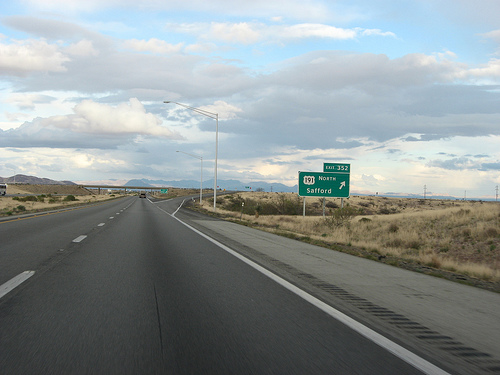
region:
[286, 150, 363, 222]
green and white traffic sign on side of road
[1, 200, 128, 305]
white dash lines on highway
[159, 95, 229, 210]
street lamps on side of highway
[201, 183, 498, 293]
field of green and yellow grass on side of highway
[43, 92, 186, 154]
white clouds in light blue sky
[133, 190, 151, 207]
car driving on highway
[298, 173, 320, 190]
black and white number on green traffic sign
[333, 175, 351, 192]
white arrow on green traffic sign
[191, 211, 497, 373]
black dash lines on side of highway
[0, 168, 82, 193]
mountains in horizon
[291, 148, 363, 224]
green and white traffic sign on side of highway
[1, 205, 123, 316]
white dash lines down center of highway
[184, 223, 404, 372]
solid white line drawn on edge of highway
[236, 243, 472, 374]
black tire tread marks on side of road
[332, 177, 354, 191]
arrow pointing right on green and white traffic sign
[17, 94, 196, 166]
white cloud in sky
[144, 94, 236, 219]
street lamp on side of road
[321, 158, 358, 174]
exit number on green traffic sign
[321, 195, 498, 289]
tall yellow grass in field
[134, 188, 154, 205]
vehicle driving on highway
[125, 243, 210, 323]
Part of the paved road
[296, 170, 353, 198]
A green and white sign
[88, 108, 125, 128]
Part of the cloud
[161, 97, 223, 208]
A light on the street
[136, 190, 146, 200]
Car in distance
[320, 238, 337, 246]
Part of the green grass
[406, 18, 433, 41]
Part of the blue sky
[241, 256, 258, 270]
Part of the white line on the road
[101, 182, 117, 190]
Part of the bridge in distance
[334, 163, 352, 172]
Numbers on the green sign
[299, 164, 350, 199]
the green highway signs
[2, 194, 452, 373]
the white lines on the road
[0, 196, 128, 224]
the yellow line on the road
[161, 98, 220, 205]
the street lights on the side of the road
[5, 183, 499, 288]
the brown grass around the road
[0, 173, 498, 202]
the mountains in the distance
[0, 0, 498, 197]
the clouds in the blue sky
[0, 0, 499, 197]
the blue sky with clouds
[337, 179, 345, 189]
the white arrow on the sign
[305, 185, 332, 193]
the word "Safford" on the sign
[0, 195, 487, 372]
the road is long and empty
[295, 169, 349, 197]
a sign is on the side of the road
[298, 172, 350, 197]
the sign has a green background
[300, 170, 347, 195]
the sign has white lettering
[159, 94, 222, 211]
a lamp post is besides the road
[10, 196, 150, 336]
the road has dash lines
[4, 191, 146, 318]
the lines are white in color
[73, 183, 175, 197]
a crossing is in the distance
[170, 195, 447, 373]
a line runs along the road